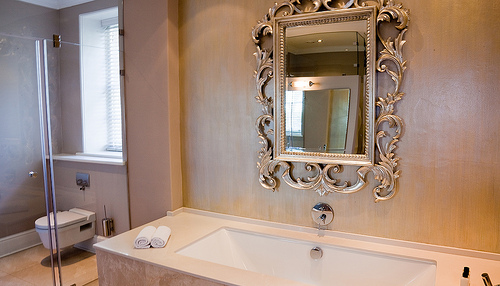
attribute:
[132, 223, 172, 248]
towels — rolled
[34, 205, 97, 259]
toilet — white, porcelain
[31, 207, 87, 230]
lid — down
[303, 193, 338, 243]
faucet — silver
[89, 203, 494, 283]
vanity — cream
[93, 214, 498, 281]
shelf — tan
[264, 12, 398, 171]
mirror — rectangular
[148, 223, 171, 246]
towel — white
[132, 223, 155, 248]
towel — white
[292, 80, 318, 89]
lights — yellow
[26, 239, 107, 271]
floor — brown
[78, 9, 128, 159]
window — white, framed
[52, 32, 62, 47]
bracket — metal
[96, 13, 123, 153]
blinds — white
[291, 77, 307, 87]
light — on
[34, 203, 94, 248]
toilet — white